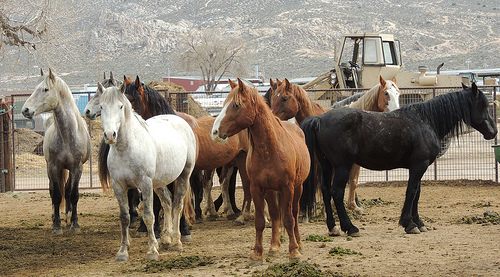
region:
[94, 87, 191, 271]
white horse standing in pasture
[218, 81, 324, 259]
brown horse standing in pasture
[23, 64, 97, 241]
gray horse standing in pasture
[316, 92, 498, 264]
black horse standing in pasture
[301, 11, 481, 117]
gray tractor on horse farm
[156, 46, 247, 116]
red and gray barn at a distance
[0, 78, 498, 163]
metal gate and fencing used to contain horses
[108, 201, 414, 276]
dirt in horse corral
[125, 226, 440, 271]
horse manure in corral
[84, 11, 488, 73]
mountain side at a distance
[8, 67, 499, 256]
horses in a pen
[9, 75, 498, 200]
a fence keeping the horses in the pen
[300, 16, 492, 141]
a tractor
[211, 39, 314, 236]
a brown and white horse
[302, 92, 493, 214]
a black horse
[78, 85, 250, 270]
a white horse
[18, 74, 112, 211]
a grey horse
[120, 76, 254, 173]
a brown and black horse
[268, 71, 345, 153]
a brown horse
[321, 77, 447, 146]
a white and brown horse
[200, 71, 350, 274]
horse is brown with white face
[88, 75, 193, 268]
one beautiful white horse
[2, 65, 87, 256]
one beautiful gray horse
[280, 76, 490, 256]
one beautiful black horse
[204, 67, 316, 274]
one beautiful brown horse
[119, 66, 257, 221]
one beautiful brown horse with black mane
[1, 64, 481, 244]
herd of eight horses all colors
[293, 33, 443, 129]
large bulldozer in background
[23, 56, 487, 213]
large chain fence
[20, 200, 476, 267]
large area of dirt ground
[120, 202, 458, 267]
patches of green horse poop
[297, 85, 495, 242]
a solid black horse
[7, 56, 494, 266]
horses standing inside the fence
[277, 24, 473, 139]
a tan tractor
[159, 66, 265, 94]
a red building in the distance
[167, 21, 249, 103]
a tree with no leaves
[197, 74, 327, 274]
a brown horse with a white stripe on its nose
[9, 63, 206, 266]
three horses that are all white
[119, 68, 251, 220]
a brown horse with a black mane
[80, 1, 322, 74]
mountains in the distance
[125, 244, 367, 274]
horse poop on the ground